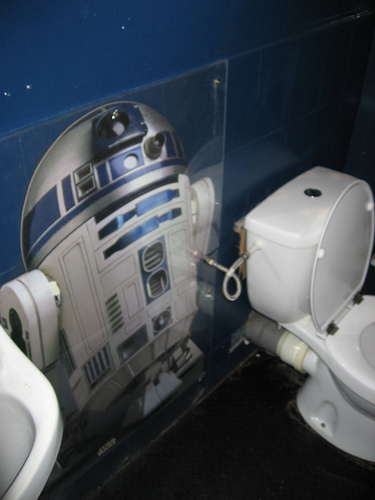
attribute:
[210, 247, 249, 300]
tube — small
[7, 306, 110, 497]
sink — small, white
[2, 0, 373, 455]
bathroom wall — blue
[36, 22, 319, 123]
wall — blue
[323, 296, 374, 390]
toilet seat — white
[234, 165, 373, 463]
white toilet — large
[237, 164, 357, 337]
toilet basin — white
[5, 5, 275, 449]
blue wall — large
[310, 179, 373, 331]
toilet lid — white